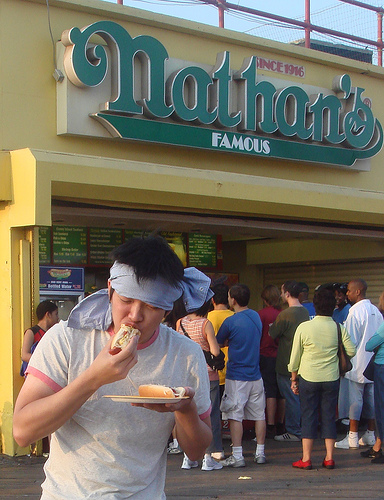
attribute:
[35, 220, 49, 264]
signs — green, white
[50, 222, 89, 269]
signs — green, white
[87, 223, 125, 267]
signs — green, white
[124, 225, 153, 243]
signs — green, white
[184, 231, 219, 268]
signs — green, white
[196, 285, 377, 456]
people — waiting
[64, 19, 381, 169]
sign — nathan's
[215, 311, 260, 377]
shirt — blue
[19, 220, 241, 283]
menu — filled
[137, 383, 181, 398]
hotdog — juicy, from Nathan's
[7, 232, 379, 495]
people — hungry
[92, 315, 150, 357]
dog — hot dog